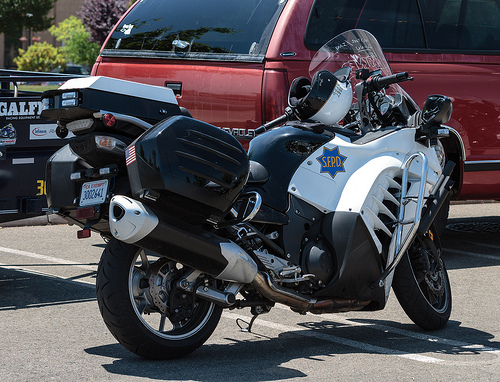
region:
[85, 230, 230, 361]
A black rubber tire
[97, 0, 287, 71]
Back window of a vehicle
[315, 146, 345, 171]
"SFPD" written on motorbike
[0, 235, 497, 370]
White lines on the pavement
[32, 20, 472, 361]
A white and black motorbike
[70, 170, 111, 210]
A white license plate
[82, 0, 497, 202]
The vehicle is red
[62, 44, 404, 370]
a bike is parked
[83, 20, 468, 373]
a bike is standing up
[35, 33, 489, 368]
a black and white bikek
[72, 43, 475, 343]
a bike with a helmet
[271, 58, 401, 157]
a black and white helmet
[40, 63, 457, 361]
a license plate on the bike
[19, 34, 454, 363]
a bike with a carriage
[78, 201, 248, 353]
a motorcycle tire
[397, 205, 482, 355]
a motorcycle tire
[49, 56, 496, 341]
a bike on the road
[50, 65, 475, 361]
a bike standing up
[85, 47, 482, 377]
a bike is parked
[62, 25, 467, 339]
a white and black bike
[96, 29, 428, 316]
a helmet on a bike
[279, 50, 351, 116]
a black and white helmet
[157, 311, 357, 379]
shadow on the ground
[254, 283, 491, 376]
white lines on the ground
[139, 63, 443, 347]
a motorcycle is parkekd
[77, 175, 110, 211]
a license plate on motorcycle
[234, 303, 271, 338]
a kick stand on a motorcycle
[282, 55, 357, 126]
a white and black helmet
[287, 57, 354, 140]
a helmet on a motorcycle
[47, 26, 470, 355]
a parked motorcycle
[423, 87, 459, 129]
a rear view mirror on a motorcycle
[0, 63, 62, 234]
a garbage dumpster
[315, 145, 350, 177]
a blue and gold decal on a motorcycle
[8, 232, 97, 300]
white lines painted on the pavement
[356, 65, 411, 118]
a handle bar on motorcycle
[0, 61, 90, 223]
A parked black truck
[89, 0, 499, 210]
A parked red van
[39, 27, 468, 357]
A parked white motorcycle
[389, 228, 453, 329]
A tire on a motorcycle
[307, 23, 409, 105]
A windshield on a motorcycle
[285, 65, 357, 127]
A helmet on a motorcycle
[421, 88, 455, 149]
a side mirror on a motorcycle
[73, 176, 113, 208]
A license plate on a motorcycle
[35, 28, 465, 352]
a police motorcycle parked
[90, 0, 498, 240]
a red Chevy truck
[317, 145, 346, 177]
blue star on side of motorcycle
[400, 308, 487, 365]
white lines on the road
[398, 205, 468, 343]
a tire on the motorcycle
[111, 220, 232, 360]
a tire on a bike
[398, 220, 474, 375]
a tire on a bike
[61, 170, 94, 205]
a license plate on the bike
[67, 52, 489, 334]
a motorcycle parked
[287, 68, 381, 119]
a helmet on the motorcycle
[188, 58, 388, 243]
a black and white motorcycle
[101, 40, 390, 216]
a red vehicle parked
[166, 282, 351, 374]
a shadow on the ground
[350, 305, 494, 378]
a white line on the pavement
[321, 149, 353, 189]
letters on the bike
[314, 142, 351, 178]
police emblem on bike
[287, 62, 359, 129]
helmet resting on gas tank of bike